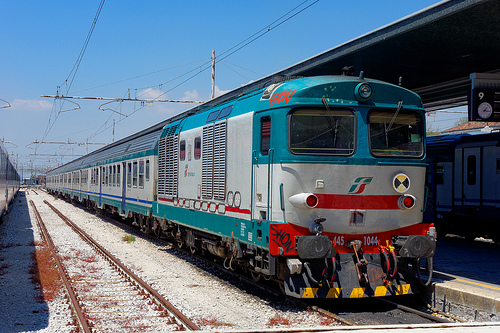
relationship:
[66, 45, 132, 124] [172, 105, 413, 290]
lines for trains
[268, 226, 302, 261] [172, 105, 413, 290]
graffiti on trains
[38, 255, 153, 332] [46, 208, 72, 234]
tracks with gravel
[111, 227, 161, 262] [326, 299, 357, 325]
grass by track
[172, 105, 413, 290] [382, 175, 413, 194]
trains with valves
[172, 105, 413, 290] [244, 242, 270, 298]
trains has wheels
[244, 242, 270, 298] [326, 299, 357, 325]
wheels on track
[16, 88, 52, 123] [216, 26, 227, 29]
cloud in sky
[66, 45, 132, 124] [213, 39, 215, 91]
lines on pole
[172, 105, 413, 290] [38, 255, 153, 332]
trains on tracks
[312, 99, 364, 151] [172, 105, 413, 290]
windshield wiper of trains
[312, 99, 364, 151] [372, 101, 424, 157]
windshield wiper in front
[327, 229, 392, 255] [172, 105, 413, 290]
numbers on trains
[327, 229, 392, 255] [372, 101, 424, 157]
numbers on front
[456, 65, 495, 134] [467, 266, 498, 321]
clock on platform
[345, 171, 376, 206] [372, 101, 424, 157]
logo on front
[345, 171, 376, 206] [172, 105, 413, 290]
logo on trains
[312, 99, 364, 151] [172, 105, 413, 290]
windshield wiper on trains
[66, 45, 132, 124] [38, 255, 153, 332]
lines over tracks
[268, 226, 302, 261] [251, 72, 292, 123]
graffiti on roof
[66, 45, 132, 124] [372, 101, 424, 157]
lines on front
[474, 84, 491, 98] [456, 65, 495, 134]
number over clock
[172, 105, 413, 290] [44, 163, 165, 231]
trains with many cars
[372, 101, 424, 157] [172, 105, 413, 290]
front of trains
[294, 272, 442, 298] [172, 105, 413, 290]
buffers on trains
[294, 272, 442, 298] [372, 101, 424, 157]
buffers on front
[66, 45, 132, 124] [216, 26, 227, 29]
lines crossing sky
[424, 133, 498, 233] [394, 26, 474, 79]
train in station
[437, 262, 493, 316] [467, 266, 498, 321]
line on platform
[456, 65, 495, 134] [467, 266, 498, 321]
clock over platform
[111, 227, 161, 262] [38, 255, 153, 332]
grass by tracks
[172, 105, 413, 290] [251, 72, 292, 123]
trains with roof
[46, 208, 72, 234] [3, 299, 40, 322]
gravel on ground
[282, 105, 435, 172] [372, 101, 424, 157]
windows in front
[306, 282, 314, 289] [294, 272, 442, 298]
stripes on buffers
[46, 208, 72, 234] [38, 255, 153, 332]
gravel by tracks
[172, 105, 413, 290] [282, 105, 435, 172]
trains with windows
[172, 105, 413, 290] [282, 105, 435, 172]
trains with windshield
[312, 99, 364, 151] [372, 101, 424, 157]
windshield wiper on front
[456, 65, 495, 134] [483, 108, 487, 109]
clock says 1:15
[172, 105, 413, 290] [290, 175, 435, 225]
trains has headlights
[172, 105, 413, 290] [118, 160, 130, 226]
trains has door